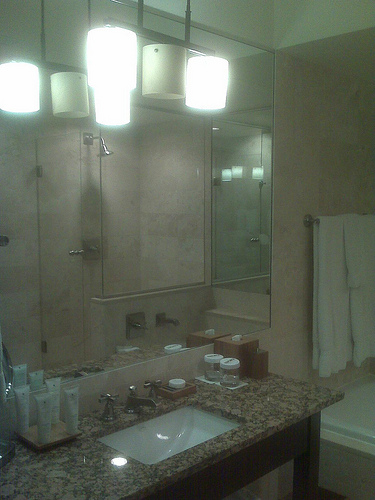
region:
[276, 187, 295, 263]
this is the wall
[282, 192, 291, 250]
the wall is white in color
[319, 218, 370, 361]
these are some towels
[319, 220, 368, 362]
the towels are white in color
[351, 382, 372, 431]
this is a bath tub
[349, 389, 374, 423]
the tub is white in color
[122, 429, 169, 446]
the bowl is white in color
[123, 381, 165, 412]
this is a tap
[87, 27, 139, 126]
Longest illuminated light hanging.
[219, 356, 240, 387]
Clear jar on the counter in front of another one with a white lid.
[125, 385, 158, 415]
Silver faucet over a sink.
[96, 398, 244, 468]
Rectangle shiny sink.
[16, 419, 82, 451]
Wood square that is holding tubes.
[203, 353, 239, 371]
Two round white lids together.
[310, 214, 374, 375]
White towels hanging on a silver bar.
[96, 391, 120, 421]
Left knob on a sink.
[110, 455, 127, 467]
Bright round white spot on the counter from the light.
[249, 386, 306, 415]
The sink counter is marble.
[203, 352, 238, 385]
Two glasses are on the counter.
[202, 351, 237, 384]
The glasses are empty.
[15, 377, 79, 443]
Bottles of cleansers are on the counter.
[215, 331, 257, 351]
A tissue holder is on the counter.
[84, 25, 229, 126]
The bathroom lights are turned on.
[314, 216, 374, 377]
Towels hang on the rack.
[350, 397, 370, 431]
The bathtub is white.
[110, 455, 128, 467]
The light is reflected onto the counter.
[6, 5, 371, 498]
A bathroom.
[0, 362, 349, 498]
A granite type counter top.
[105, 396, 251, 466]
A white sink.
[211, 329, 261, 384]
A wooden tissue box.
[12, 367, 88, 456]
Four containers of liquid on a plate.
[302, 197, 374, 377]
White towels hanging over the bathtub.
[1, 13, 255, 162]
Lights hanging above the sink.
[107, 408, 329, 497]
Wooden cabinet under the sink.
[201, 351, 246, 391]
Two glass jars with white lids on the counter.